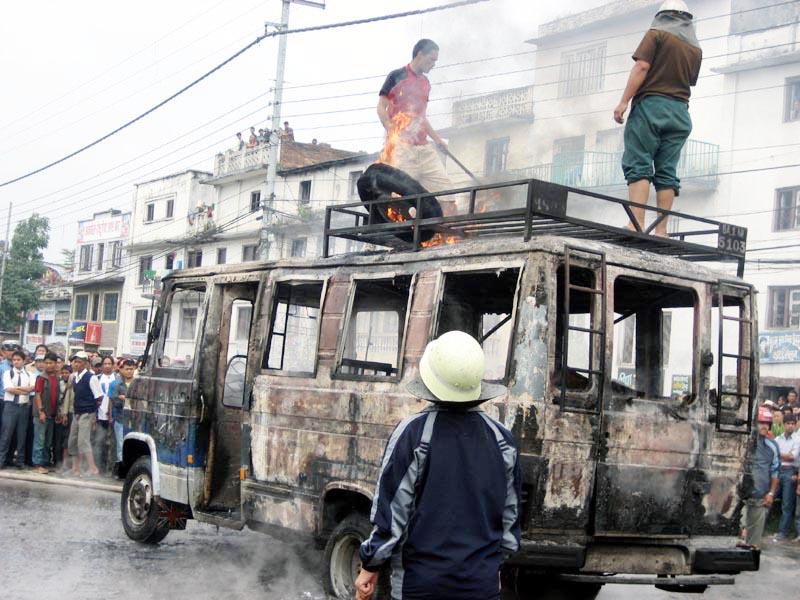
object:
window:
[610, 273, 697, 404]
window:
[554, 263, 598, 393]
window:
[430, 266, 521, 384]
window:
[334, 273, 419, 378]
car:
[118, 234, 762, 600]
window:
[156, 281, 210, 367]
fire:
[374, 105, 498, 247]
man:
[377, 38, 456, 241]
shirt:
[378, 63, 432, 145]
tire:
[122, 455, 172, 543]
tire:
[322, 513, 382, 600]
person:
[0, 352, 34, 472]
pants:
[0, 402, 31, 469]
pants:
[68, 411, 93, 456]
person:
[62, 349, 101, 479]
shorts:
[391, 144, 456, 201]